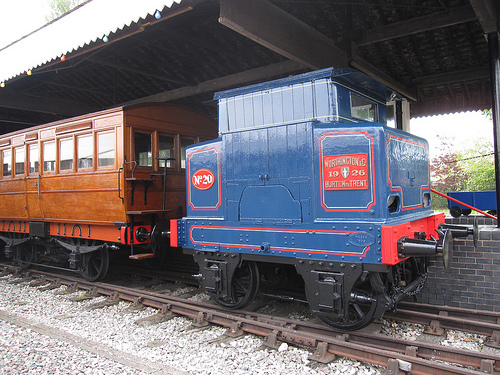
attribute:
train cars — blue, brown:
[1, 73, 444, 310]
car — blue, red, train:
[165, 59, 478, 335]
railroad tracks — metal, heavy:
[0, 257, 498, 372]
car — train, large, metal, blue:
[171, 68, 451, 342]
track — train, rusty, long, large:
[53, 267, 473, 373]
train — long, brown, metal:
[8, 103, 189, 279]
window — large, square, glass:
[88, 122, 131, 173]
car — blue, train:
[179, 76, 443, 315]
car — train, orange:
[5, 97, 176, 277]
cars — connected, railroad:
[18, 78, 458, 328]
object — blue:
[421, 187, 497, 225]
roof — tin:
[91, 23, 200, 78]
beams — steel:
[252, 26, 335, 58]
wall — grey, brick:
[461, 259, 497, 309]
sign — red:
[178, 168, 240, 218]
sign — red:
[303, 143, 373, 216]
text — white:
[336, 157, 364, 190]